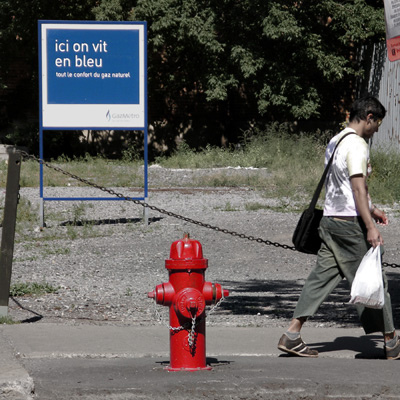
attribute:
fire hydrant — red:
[149, 230, 229, 369]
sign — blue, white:
[37, 21, 148, 131]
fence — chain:
[4, 140, 400, 344]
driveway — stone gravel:
[2, 185, 400, 328]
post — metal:
[2, 150, 19, 309]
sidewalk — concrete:
[6, 321, 400, 359]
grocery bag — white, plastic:
[355, 243, 386, 312]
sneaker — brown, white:
[279, 338, 318, 358]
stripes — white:
[290, 341, 305, 352]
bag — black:
[298, 210, 321, 250]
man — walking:
[282, 92, 400, 363]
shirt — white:
[323, 126, 371, 218]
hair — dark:
[347, 96, 384, 119]